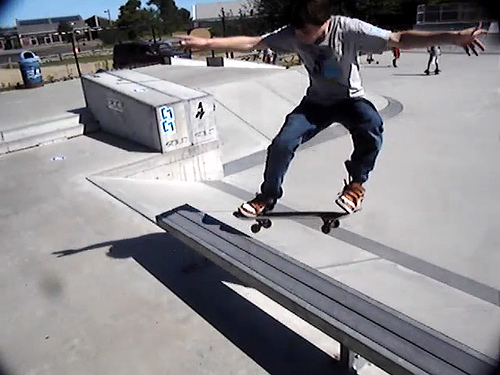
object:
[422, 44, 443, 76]
person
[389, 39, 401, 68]
person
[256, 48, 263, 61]
person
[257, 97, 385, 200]
jeans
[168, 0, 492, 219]
boy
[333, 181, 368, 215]
shoes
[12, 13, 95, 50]
house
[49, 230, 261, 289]
shadow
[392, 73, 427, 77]
shadow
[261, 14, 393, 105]
shirt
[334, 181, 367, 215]
sneakers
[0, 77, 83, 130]
street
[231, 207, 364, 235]
skate board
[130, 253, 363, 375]
shadow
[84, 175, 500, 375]
ramp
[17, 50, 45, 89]
cans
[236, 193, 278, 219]
shoes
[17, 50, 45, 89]
garbage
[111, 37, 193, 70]
suv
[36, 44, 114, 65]
parking lot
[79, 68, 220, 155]
shipping container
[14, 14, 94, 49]
building